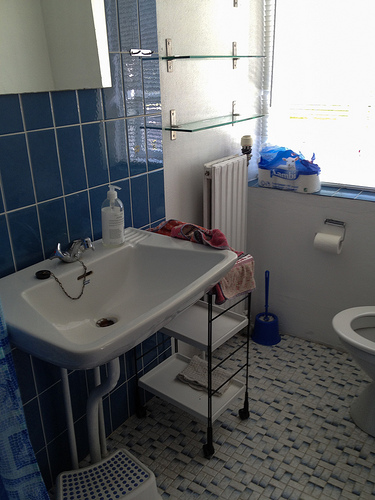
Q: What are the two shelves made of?
A: Glass.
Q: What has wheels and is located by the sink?
A: Cart.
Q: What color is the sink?
A: White.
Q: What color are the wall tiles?
A: Blue.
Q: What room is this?
A: Bathroom.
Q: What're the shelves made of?
A: Glass.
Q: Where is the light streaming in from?
A: Window.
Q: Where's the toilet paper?
A: Against the far wall.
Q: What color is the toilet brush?
A: Blue.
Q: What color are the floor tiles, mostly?
A: White.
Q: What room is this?
A: A bathroom.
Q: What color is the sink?
A: White.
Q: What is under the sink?
A: A stepstool.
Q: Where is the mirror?
A: Above the sink.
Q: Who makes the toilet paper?
A: Lambi.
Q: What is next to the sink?
A: A cart.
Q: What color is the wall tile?
A: Blue.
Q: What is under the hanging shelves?
A: A heater.